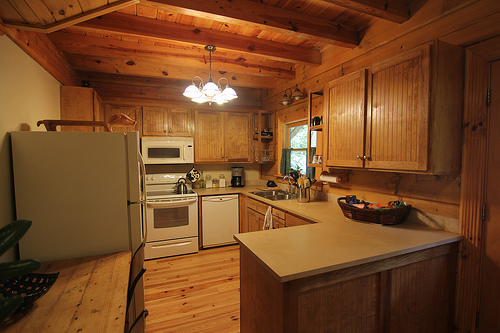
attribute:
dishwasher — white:
[200, 192, 240, 250]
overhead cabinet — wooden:
[320, 69, 365, 172]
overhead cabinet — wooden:
[363, 38, 462, 177]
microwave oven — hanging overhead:
[140, 135, 195, 166]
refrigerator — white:
[6, 122, 155, 272]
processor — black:
[226, 158, 252, 197]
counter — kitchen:
[243, 204, 458, 280]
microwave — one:
[141, 129, 201, 166]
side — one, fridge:
[8, 125, 128, 245]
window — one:
[281, 118, 321, 183]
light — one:
[180, 81, 245, 106]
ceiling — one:
[22, 5, 395, 84]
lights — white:
[186, 73, 237, 108]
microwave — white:
[131, 126, 201, 172]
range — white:
[139, 169, 201, 257]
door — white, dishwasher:
[201, 189, 240, 249]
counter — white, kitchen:
[235, 202, 449, 283]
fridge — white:
[9, 123, 142, 256]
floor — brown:
[150, 256, 245, 325]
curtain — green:
[279, 139, 329, 175]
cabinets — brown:
[314, 60, 442, 171]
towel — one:
[253, 201, 283, 234]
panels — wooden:
[322, 169, 450, 205]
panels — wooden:
[316, 19, 486, 55]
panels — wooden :
[163, 257, 233, 332]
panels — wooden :
[73, 264, 131, 332]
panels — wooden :
[150, 262, 223, 283]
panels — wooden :
[90, 27, 275, 87]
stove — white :
[150, 159, 197, 261]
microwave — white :
[137, 131, 210, 171]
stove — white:
[144, 174, 198, 262]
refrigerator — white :
[13, 123, 147, 259]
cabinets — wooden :
[60, 79, 449, 185]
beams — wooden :
[25, 16, 355, 101]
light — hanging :
[183, 43, 243, 108]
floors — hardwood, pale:
[147, 254, 239, 330]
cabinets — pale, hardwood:
[63, 81, 479, 184]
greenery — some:
[287, 126, 313, 168]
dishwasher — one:
[200, 185, 237, 254]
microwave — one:
[137, 128, 197, 166]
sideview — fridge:
[16, 120, 152, 245]